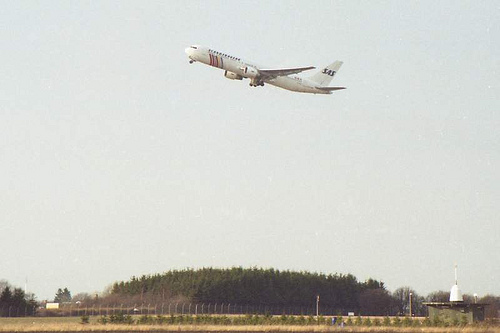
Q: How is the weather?
A: It is cloudless.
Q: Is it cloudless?
A: Yes, it is cloudless.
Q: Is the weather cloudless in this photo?
A: Yes, it is cloudless.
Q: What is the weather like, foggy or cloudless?
A: It is cloudless.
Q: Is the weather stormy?
A: No, it is cloudless.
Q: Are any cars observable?
A: No, there are no cars.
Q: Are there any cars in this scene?
A: No, there are no cars.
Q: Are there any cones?
A: No, there are no cones.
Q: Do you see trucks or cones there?
A: No, there are no cones or trucks.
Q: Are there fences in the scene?
A: Yes, there is a fence.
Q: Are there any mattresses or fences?
A: Yes, there is a fence.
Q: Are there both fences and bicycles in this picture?
A: No, there is a fence but no bicycles.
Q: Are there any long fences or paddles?
A: Yes, there is a long fence.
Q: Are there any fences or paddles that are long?
A: Yes, the fence is long.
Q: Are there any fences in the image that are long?
A: Yes, there is a long fence.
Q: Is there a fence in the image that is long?
A: Yes, there is a fence that is long.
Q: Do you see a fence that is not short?
A: Yes, there is a long fence.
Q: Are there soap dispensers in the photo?
A: No, there are no soap dispensers.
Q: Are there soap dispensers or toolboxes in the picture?
A: No, there are no soap dispensers or toolboxes.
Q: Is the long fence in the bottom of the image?
A: Yes, the fence is in the bottom of the image.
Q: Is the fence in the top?
A: No, the fence is in the bottom of the image.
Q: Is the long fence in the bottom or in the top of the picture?
A: The fence is in the bottom of the image.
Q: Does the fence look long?
A: Yes, the fence is long.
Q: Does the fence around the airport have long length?
A: Yes, the fence is long.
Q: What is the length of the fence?
A: The fence is long.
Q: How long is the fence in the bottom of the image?
A: The fence is long.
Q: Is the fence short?
A: No, the fence is long.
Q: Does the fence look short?
A: No, the fence is long.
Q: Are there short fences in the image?
A: No, there is a fence but it is long.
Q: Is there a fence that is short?
A: No, there is a fence but it is long.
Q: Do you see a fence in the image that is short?
A: No, there is a fence but it is long.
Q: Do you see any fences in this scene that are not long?
A: No, there is a fence but it is long.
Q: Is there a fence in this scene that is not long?
A: No, there is a fence but it is long.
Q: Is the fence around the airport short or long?
A: The fence is long.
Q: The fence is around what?
A: The fence is around the airport.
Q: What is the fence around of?
A: The fence is around the airport.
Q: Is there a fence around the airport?
A: Yes, there is a fence around the airport.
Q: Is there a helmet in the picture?
A: No, there are no helmets.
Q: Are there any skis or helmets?
A: No, there are no helmets or skis.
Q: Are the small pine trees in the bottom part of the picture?
A: Yes, the pines are in the bottom of the image.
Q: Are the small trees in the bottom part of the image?
A: Yes, the pines are in the bottom of the image.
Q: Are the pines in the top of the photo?
A: No, the pines are in the bottom of the image.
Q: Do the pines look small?
A: Yes, the pines are small.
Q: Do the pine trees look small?
A: Yes, the pine trees are small.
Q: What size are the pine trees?
A: The pine trees are small.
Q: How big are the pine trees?
A: The pine trees are small.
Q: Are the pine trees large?
A: No, the pine trees are small.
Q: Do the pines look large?
A: No, the pines are small.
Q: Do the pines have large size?
A: No, the pines are small.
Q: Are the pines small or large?
A: The pines are small.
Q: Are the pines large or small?
A: The pines are small.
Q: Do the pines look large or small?
A: The pines are small.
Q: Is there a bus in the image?
A: No, there are no buses.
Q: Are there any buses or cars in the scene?
A: No, there are no buses or cars.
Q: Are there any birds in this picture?
A: No, there are no birds.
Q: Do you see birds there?
A: No, there are no birds.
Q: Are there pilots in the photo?
A: No, there are no pilots.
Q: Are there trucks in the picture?
A: No, there are no trucks.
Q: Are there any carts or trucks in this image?
A: No, there are no trucks or carts.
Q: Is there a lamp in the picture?
A: No, there are no lamps.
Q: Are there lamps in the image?
A: No, there are no lamps.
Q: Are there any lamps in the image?
A: No, there are no lamps.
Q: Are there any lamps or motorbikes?
A: No, there are no lamps or motorbikes.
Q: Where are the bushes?
A: The bushes are on the runway.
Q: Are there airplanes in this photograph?
A: Yes, there is an airplane.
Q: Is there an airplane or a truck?
A: Yes, there is an airplane.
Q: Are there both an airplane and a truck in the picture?
A: No, there is an airplane but no trucks.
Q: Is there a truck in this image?
A: No, there are no trucks.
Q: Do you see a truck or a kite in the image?
A: No, there are no trucks or kites.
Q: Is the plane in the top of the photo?
A: Yes, the plane is in the top of the image.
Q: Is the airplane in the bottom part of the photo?
A: No, the airplane is in the top of the image.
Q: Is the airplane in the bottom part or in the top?
A: The airplane is in the top of the image.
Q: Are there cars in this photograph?
A: No, there are no cars.